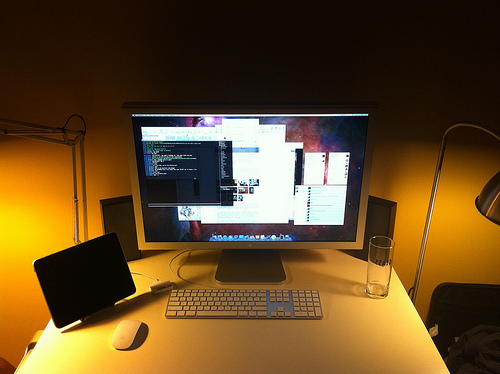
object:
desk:
[13, 249, 451, 373]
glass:
[363, 234, 395, 299]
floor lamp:
[410, 123, 499, 305]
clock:
[338, 238, 357, 241]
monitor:
[131, 114, 369, 242]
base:
[214, 249, 288, 285]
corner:
[328, 81, 380, 99]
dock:
[207, 233, 294, 243]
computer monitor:
[122, 101, 378, 285]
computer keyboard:
[164, 288, 323, 319]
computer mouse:
[112, 318, 149, 350]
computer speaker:
[99, 194, 143, 261]